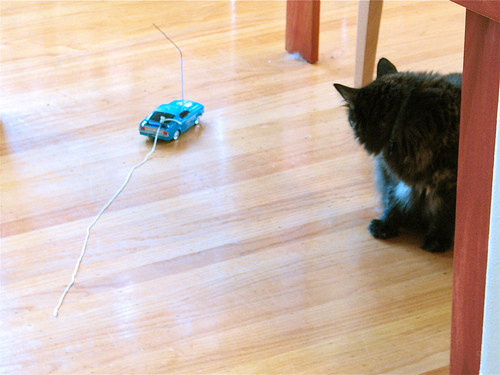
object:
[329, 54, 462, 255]
cat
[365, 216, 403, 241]
paw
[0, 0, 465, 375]
floor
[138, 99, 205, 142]
car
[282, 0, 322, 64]
leg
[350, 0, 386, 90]
leg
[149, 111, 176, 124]
window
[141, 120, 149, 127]
lights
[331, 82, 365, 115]
ear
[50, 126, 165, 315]
string